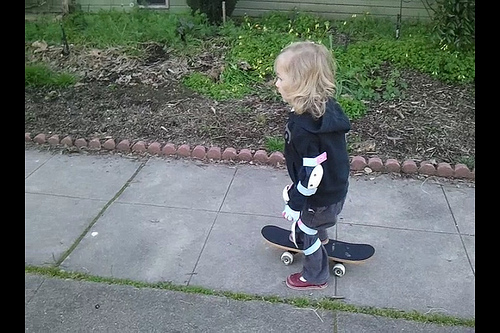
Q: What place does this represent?
A: It represents the sidewalk.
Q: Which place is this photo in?
A: It is at the sidewalk.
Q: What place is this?
A: It is a sidewalk.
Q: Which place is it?
A: It is a sidewalk.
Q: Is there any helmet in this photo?
A: No, there are no helmets.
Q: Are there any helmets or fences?
A: No, there are no helmets or fences.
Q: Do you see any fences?
A: No, there are no fences.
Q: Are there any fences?
A: No, there are no fences.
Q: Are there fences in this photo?
A: No, there are no fences.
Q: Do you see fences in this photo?
A: No, there are no fences.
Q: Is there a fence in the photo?
A: No, there are no fences.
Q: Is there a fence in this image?
A: No, there are no fences.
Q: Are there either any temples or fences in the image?
A: No, there are no fences or temples.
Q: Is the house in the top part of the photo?
A: Yes, the house is in the top of the image.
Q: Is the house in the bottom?
A: No, the house is in the top of the image.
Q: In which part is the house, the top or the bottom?
A: The house is in the top of the image.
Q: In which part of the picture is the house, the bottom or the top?
A: The house is in the top of the image.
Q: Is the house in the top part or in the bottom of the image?
A: The house is in the top of the image.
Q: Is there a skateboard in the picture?
A: Yes, there is a skateboard.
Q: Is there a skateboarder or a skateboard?
A: Yes, there is a skateboard.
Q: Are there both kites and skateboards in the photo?
A: No, there is a skateboard but no kites.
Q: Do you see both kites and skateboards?
A: No, there is a skateboard but no kites.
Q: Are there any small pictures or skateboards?
A: Yes, there is a small skateboard.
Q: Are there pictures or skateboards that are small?
A: Yes, the skateboard is small.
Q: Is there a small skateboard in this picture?
A: Yes, there is a small skateboard.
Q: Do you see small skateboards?
A: Yes, there is a small skateboard.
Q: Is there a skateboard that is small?
A: Yes, there is a skateboard that is small.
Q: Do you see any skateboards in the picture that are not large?
A: Yes, there is a small skateboard.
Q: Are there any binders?
A: No, there are no binders.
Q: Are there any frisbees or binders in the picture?
A: No, there are no binders or frisbees.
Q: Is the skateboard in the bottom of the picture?
A: Yes, the skateboard is in the bottom of the image.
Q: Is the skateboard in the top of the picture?
A: No, the skateboard is in the bottom of the image.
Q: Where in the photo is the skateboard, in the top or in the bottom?
A: The skateboard is in the bottom of the image.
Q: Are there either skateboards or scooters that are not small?
A: No, there is a skateboard but it is small.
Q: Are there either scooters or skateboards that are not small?
A: No, there is a skateboard but it is small.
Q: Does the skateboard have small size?
A: Yes, the skateboard is small.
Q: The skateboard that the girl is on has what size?
A: The skateboard is small.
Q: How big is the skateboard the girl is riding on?
A: The skateboard is small.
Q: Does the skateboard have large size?
A: No, the skateboard is small.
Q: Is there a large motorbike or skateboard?
A: No, there is a skateboard but it is small.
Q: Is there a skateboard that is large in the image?
A: No, there is a skateboard but it is small.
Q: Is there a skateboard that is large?
A: No, there is a skateboard but it is small.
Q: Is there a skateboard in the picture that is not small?
A: No, there is a skateboard but it is small.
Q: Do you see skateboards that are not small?
A: No, there is a skateboard but it is small.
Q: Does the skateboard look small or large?
A: The skateboard is small.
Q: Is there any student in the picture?
A: No, there are no students.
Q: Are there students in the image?
A: No, there are no students.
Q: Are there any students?
A: No, there are no students.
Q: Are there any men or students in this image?
A: No, there are no students or men.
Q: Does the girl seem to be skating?
A: Yes, the girl is skating.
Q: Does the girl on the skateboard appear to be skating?
A: Yes, the girl is skating.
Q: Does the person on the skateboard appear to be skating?
A: Yes, the girl is skating.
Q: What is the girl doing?
A: The girl is skating.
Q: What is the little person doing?
A: The girl is skating.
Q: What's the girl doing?
A: The girl is skating.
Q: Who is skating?
A: The girl is skating.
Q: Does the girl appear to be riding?
A: No, the girl is skating.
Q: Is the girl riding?
A: No, the girl is skating.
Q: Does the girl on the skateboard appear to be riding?
A: No, the girl is skating.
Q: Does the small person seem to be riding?
A: No, the girl is skating.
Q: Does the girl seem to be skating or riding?
A: The girl is skating.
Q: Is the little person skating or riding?
A: The girl is skating.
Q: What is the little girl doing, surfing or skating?
A: The girl is skating.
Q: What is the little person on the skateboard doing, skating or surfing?
A: The girl is skating.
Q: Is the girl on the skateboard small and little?
A: Yes, the girl is small and little.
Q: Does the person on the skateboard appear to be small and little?
A: Yes, the girl is small and little.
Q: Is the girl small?
A: Yes, the girl is small.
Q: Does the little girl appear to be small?
A: Yes, the girl is small.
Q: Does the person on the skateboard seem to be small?
A: Yes, the girl is small.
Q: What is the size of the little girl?
A: The girl is small.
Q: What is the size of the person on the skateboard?
A: The girl is small.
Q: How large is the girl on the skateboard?
A: The girl is small.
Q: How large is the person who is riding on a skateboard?
A: The girl is small.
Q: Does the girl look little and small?
A: Yes, the girl is little and small.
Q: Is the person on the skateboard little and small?
A: Yes, the girl is little and small.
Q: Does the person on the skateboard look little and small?
A: Yes, the girl is little and small.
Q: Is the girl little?
A: Yes, the girl is little.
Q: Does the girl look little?
A: Yes, the girl is little.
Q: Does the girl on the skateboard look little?
A: Yes, the girl is little.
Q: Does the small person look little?
A: Yes, the girl is little.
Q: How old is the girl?
A: The girl is little.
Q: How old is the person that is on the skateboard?
A: The girl is little.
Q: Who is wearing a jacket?
A: The girl is wearing a jacket.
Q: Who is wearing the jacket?
A: The girl is wearing a jacket.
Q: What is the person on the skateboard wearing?
A: The girl is wearing a jacket.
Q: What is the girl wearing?
A: The girl is wearing a jacket.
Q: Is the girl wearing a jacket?
A: Yes, the girl is wearing a jacket.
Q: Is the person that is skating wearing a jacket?
A: Yes, the girl is wearing a jacket.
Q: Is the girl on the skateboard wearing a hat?
A: No, the girl is wearing a jacket.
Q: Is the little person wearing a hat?
A: No, the girl is wearing a jacket.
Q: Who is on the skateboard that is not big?
A: The girl is on the skateboard.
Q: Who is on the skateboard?
A: The girl is on the skateboard.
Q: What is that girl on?
A: The girl is on the skateboard.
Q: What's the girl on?
A: The girl is on the skateboard.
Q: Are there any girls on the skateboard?
A: Yes, there is a girl on the skateboard.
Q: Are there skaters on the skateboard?
A: No, there is a girl on the skateboard.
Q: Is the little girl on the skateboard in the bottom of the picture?
A: Yes, the girl is on the skateboard.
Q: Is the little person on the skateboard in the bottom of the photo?
A: Yes, the girl is on the skateboard.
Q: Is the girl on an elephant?
A: No, the girl is on the skateboard.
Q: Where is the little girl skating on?
A: The girl is skating on the side walk.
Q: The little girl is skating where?
A: The girl is skating on the side walk.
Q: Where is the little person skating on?
A: The girl is skating on the side walk.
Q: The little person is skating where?
A: The girl is skating on the side walk.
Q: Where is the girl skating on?
A: The girl is skating on the side walk.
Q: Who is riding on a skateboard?
A: The girl is riding on a skateboard.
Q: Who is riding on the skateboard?
A: The girl is riding on a skateboard.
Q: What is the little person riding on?
A: The girl is riding on a skateboard.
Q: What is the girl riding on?
A: The girl is riding on a skateboard.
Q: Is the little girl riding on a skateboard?
A: Yes, the girl is riding on a skateboard.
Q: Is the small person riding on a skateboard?
A: Yes, the girl is riding on a skateboard.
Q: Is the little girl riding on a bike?
A: No, the girl is riding on a skateboard.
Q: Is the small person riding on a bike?
A: No, the girl is riding on a skateboard.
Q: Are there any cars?
A: No, there are no cars.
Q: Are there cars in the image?
A: No, there are no cars.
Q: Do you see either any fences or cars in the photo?
A: No, there are no cars or fences.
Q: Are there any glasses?
A: No, there are no glasses.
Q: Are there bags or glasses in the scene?
A: No, there are no glasses or bags.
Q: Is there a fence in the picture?
A: No, there are no fences.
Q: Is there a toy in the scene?
A: No, there are no toys.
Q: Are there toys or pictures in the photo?
A: No, there are no toys or pictures.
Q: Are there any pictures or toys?
A: No, there are no toys or pictures.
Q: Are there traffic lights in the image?
A: No, there are no traffic lights.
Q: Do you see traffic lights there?
A: No, there are no traffic lights.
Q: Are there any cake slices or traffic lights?
A: No, there are no traffic lights or cake slices.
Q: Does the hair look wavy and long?
A: Yes, the hair is wavy and long.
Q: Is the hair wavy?
A: Yes, the hair is wavy.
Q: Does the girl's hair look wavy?
A: Yes, the hair is wavy.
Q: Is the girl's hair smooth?
A: No, the hair is wavy.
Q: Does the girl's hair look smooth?
A: No, the hair is wavy.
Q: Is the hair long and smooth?
A: No, the hair is long but wavy.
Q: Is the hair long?
A: Yes, the hair is long.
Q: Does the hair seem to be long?
A: Yes, the hair is long.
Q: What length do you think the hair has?
A: The hair has long length.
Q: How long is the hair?
A: The hair is long.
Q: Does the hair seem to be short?
A: No, the hair is long.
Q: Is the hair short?
A: No, the hair is long.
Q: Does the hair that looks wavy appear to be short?
A: No, the hair is long.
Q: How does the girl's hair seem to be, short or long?
A: The hair is long.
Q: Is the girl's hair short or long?
A: The hair is long.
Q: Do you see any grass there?
A: Yes, there is grass.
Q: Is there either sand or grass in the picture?
A: Yes, there is grass.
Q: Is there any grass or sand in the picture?
A: Yes, there is grass.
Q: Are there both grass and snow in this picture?
A: No, there is grass but no snow.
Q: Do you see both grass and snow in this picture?
A: No, there is grass but no snow.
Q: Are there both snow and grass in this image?
A: No, there is grass but no snow.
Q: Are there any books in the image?
A: No, there are no books.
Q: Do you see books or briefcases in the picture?
A: No, there are no books or briefcases.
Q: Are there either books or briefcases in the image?
A: No, there are no books or briefcases.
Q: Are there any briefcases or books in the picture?
A: No, there are no books or briefcases.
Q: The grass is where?
A: The grass is on the sidewalk.